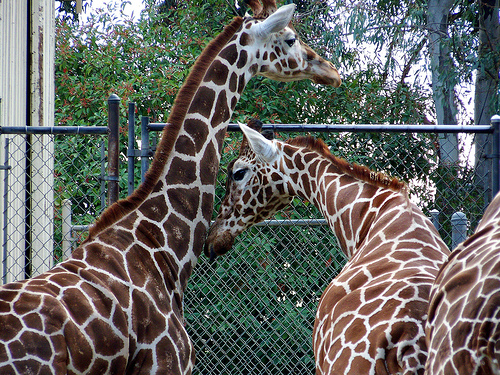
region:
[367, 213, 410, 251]
Brown and white patch on giraffe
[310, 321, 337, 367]
Brown and white patch on giraffe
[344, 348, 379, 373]
Brown and white patch on giraffe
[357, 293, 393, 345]
Brown and white patch on giraffe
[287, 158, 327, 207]
Brown and white patch on giraffe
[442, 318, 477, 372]
Brown and white patch on giraffe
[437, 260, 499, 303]
Brown and white patch on giraffe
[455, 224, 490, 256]
Brown and white patch on giraffe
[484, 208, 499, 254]
Brown and white patch on giraffe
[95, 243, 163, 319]
Brown and white patch on giraffe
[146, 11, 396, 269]
two different giraffes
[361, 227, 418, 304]
brown spots on giraffe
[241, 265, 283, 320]
fence in front of giraffe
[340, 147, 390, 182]
hair on back of giraffe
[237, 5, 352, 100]
head of the giraffe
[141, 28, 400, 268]
two animals next to each other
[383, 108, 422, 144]
bar on the fence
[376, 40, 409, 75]
sky above trees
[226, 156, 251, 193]
eye of the giraffe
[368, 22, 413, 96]
trees behind the fence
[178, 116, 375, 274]
giraffe sniffing other giraffe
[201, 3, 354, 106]
giraffe looking behind fence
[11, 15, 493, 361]
3 giraffes behind fence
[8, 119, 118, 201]
wired meshed fence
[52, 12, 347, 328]
tall plants behind fence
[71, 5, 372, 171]
giraffe is taller than fence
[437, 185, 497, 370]
partially seen giraffe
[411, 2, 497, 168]
tall trees behind fence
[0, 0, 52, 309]
white structure behind fence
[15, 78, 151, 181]
fence partially painted blue with traces of corosion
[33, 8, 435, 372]
giraffes behind a fence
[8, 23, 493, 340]
giraffes behind a tall fence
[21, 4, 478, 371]
giraffes behind a chainlinked fence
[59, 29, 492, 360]
a tall giraffe behind a fence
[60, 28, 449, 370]
a tall giraffe behind a tall fence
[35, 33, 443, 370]
girafes behind a tall chainlink fence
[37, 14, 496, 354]
a fence in front of giraffes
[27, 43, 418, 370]
a tall fence in front of giraffes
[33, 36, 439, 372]
a tall fence in front of tall giraffes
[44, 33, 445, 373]
a chainlink fence in front of giraffes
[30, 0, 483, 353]
There are three giraffes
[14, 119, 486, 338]
There is a metal fence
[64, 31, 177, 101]
There are red spots in the tree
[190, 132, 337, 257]
The giraffe is looking at the other giraffe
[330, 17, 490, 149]
It is later in the day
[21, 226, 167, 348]
The giraffe has brown spots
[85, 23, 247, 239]
The giraffe has a long mane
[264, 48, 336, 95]
The giraffe has a long snout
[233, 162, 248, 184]
The giraffe has black eyes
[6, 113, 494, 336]
The giraffes are fenced in